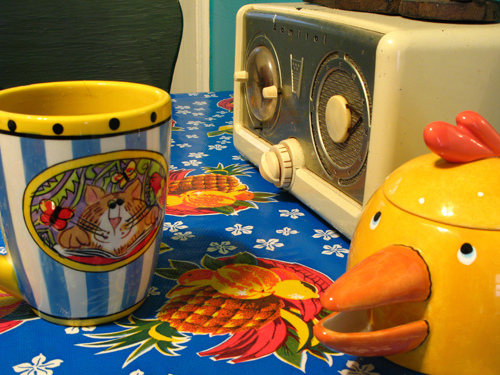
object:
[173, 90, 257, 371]
table cloth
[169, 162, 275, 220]
fruit designs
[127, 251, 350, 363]
fruit designs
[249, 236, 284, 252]
white flowers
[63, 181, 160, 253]
cat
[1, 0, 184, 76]
black chair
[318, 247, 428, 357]
beak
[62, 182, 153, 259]
dog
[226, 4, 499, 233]
timer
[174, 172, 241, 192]
fruit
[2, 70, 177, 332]
cup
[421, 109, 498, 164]
feather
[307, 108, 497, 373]
jar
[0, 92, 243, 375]
table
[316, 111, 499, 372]
bowl/table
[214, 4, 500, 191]
radio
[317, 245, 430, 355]
nose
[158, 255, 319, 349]
pineapple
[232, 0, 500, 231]
toaster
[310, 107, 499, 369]
chicken head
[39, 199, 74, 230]
butterfly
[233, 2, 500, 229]
appliance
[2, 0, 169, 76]
back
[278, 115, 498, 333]
bowl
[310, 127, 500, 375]
chicken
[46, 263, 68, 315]
blue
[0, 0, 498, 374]
area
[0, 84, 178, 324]
cartoon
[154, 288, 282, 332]
fruits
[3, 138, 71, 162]
strips